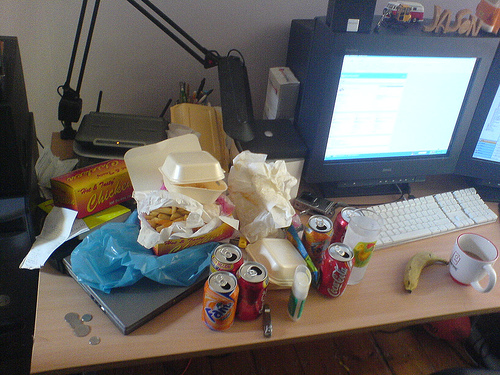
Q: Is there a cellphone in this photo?
A: No, there are no cell phones.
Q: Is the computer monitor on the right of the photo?
A: Yes, the computer monitor is on the right of the image.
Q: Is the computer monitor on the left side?
A: No, the computer monitor is on the right of the image.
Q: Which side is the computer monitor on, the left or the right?
A: The computer monitor is on the right of the image.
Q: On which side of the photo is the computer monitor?
A: The computer monitor is on the right of the image.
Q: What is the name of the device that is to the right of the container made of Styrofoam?
A: The device is a computer monitor.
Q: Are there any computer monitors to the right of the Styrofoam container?
A: Yes, there is a computer monitor to the right of the container.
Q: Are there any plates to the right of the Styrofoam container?
A: No, there is a computer monitor to the right of the container.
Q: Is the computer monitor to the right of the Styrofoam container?
A: Yes, the computer monitor is to the right of the container.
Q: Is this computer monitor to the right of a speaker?
A: No, the computer monitor is to the right of the container.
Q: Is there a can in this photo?
A: Yes, there is a can.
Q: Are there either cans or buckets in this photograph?
A: Yes, there is a can.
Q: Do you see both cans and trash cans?
A: No, there is a can but no trash cans.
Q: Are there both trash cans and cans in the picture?
A: No, there is a can but no trash cans.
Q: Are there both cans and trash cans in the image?
A: No, there is a can but no trash cans.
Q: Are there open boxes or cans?
A: Yes, there is an open can.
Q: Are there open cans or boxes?
A: Yes, there is an open can.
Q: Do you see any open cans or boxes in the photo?
A: Yes, there is an open can.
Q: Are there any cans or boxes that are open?
A: Yes, the can is open.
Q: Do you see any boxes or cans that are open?
A: Yes, the can is open.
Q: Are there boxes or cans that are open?
A: Yes, the can is open.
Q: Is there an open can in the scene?
A: Yes, there is an open can.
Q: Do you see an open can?
A: Yes, there is an open can.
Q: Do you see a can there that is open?
A: Yes, there is a can that is open.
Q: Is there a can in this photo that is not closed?
A: Yes, there is a open can.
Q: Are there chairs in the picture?
A: No, there are no chairs.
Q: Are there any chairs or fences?
A: No, there are no chairs or fences.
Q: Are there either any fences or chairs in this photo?
A: No, there are no chairs or fences.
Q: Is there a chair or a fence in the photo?
A: No, there are no chairs or fences.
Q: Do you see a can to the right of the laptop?
A: Yes, there is a can to the right of the laptop.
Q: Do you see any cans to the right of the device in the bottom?
A: Yes, there is a can to the right of the laptop.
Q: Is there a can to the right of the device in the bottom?
A: Yes, there is a can to the right of the laptop.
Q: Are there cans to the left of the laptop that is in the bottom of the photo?
A: No, the can is to the right of the laptop.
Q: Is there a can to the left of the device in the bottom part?
A: No, the can is to the right of the laptop.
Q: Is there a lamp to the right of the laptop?
A: No, there is a can to the right of the laptop.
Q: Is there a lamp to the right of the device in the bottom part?
A: No, there is a can to the right of the laptop.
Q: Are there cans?
A: Yes, there is a can.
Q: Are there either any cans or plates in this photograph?
A: Yes, there is a can.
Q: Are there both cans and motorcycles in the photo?
A: No, there is a can but no motorcycles.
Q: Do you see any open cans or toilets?
A: Yes, there is an open can.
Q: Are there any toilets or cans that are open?
A: Yes, the can is open.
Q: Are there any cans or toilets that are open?
A: Yes, the can is open.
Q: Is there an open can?
A: Yes, there is an open can.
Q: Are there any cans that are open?
A: Yes, there is a can that is open.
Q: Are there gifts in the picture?
A: No, there are no gifts.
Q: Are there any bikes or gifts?
A: No, there are no gifts or bikes.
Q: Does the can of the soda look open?
A: Yes, the can is open.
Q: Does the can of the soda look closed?
A: No, the can is open.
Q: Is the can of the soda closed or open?
A: The can is open.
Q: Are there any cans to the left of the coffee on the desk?
A: Yes, there is a can to the left of the coffee.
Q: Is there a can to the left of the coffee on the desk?
A: Yes, there is a can to the left of the coffee.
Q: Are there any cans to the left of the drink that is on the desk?
A: Yes, there is a can to the left of the coffee.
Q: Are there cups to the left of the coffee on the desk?
A: No, there is a can to the left of the coffee.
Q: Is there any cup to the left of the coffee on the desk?
A: No, there is a can to the left of the coffee.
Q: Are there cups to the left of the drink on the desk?
A: No, there is a can to the left of the coffee.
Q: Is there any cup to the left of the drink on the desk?
A: No, there is a can to the left of the coffee.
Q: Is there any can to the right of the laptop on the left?
A: Yes, there is a can to the right of the laptop computer.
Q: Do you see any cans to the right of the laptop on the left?
A: Yes, there is a can to the right of the laptop computer.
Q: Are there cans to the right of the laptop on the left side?
A: Yes, there is a can to the right of the laptop computer.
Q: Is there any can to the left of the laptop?
A: No, the can is to the right of the laptop.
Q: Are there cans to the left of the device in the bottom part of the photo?
A: No, the can is to the right of the laptop.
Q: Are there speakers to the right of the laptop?
A: No, there is a can to the right of the laptop.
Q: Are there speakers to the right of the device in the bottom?
A: No, there is a can to the right of the laptop.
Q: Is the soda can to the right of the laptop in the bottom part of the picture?
A: Yes, the can is to the right of the laptop.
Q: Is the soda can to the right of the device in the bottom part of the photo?
A: Yes, the can is to the right of the laptop.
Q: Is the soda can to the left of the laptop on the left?
A: No, the can is to the right of the laptop computer.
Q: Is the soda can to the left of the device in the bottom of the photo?
A: No, the can is to the right of the laptop computer.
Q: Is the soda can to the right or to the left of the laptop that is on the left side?
A: The can is to the right of the laptop.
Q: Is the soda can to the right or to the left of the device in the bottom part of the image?
A: The can is to the right of the laptop.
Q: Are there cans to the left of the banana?
A: Yes, there is a can to the left of the banana.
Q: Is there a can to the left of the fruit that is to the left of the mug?
A: Yes, there is a can to the left of the banana.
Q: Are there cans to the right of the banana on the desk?
A: No, the can is to the left of the banana.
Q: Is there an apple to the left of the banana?
A: No, there is a can to the left of the banana.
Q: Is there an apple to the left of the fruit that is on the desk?
A: No, there is a can to the left of the banana.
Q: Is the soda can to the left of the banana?
A: Yes, the can is to the left of the banana.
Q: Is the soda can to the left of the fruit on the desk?
A: Yes, the can is to the left of the banana.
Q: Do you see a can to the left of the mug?
A: Yes, there is a can to the left of the mug.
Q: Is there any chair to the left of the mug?
A: No, there is a can to the left of the mug.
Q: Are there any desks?
A: Yes, there is a desk.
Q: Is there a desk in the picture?
A: Yes, there is a desk.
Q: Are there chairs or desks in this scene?
A: Yes, there is a desk.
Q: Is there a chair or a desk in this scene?
A: Yes, there is a desk.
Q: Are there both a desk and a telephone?
A: No, there is a desk but no phones.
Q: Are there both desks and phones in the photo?
A: No, there is a desk but no phones.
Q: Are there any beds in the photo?
A: No, there are no beds.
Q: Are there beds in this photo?
A: No, there are no beds.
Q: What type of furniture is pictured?
A: The furniture is a desk.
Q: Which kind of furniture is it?
A: The piece of furniture is a desk.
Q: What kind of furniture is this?
A: This is a desk.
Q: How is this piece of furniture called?
A: This is a desk.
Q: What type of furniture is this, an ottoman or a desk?
A: This is a desk.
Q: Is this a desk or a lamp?
A: This is a desk.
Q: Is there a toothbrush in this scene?
A: No, there are no toothbrushes.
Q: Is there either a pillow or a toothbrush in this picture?
A: No, there are no toothbrushes or pillows.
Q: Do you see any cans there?
A: Yes, there is a can.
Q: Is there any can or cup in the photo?
A: Yes, there is a can.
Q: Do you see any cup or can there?
A: Yes, there is a can.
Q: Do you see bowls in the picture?
A: No, there are no bowls.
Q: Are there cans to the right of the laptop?
A: Yes, there is a can to the right of the laptop.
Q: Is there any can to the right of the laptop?
A: Yes, there is a can to the right of the laptop.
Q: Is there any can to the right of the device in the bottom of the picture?
A: Yes, there is a can to the right of the laptop.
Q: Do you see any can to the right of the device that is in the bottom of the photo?
A: Yes, there is a can to the right of the laptop.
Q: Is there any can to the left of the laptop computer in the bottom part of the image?
A: No, the can is to the right of the laptop.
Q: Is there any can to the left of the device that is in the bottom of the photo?
A: No, the can is to the right of the laptop.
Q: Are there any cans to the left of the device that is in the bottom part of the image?
A: No, the can is to the right of the laptop.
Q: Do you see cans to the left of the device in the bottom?
A: No, the can is to the right of the laptop.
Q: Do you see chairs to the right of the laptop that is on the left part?
A: No, there is a can to the right of the laptop.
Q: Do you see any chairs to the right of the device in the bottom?
A: No, there is a can to the right of the laptop.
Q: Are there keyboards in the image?
A: Yes, there is a keyboard.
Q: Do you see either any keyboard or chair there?
A: Yes, there is a keyboard.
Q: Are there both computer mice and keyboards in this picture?
A: No, there is a keyboard but no computer mice.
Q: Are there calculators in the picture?
A: No, there are no calculators.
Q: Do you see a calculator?
A: No, there are no calculators.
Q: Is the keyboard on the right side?
A: Yes, the keyboard is on the right of the image.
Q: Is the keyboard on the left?
A: No, the keyboard is on the right of the image.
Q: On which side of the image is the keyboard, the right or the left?
A: The keyboard is on the right of the image.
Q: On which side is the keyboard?
A: The keyboard is on the right of the image.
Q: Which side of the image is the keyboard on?
A: The keyboard is on the right of the image.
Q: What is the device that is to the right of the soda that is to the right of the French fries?
A: The device is a keyboard.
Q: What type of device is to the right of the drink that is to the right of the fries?
A: The device is a keyboard.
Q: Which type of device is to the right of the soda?
A: The device is a keyboard.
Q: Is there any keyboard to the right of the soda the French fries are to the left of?
A: Yes, there is a keyboard to the right of the soda.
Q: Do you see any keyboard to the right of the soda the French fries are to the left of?
A: Yes, there is a keyboard to the right of the soda.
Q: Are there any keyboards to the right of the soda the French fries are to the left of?
A: Yes, there is a keyboard to the right of the soda.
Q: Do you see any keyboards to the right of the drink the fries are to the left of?
A: Yes, there is a keyboard to the right of the soda.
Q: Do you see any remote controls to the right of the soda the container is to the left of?
A: No, there is a keyboard to the right of the soda.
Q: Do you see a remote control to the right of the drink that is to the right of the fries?
A: No, there is a keyboard to the right of the soda.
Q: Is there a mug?
A: Yes, there is a mug.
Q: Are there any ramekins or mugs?
A: Yes, there is a mug.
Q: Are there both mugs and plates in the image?
A: No, there is a mug but no plates.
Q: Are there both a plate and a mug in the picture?
A: No, there is a mug but no plates.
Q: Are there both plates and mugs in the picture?
A: No, there is a mug but no plates.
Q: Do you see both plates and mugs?
A: No, there is a mug but no plates.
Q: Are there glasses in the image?
A: No, there are no glasses.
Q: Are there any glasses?
A: No, there are no glasses.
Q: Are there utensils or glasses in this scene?
A: No, there are no glasses or utensils.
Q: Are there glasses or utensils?
A: No, there are no glasses or utensils.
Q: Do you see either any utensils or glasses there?
A: No, there are no glasses or utensils.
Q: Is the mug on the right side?
A: Yes, the mug is on the right of the image.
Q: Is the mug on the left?
A: No, the mug is on the right of the image.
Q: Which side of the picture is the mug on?
A: The mug is on the right of the image.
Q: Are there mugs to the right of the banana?
A: Yes, there is a mug to the right of the banana.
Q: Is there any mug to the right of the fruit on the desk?
A: Yes, there is a mug to the right of the banana.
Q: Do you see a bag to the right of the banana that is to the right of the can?
A: No, there is a mug to the right of the banana.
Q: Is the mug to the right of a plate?
A: No, the mug is to the right of the banana.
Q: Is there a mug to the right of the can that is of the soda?
A: Yes, there is a mug to the right of the can.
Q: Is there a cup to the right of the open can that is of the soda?
A: No, there is a mug to the right of the can.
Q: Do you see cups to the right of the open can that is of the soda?
A: No, there is a mug to the right of the can.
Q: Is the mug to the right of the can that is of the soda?
A: Yes, the mug is to the right of the can.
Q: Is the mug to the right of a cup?
A: No, the mug is to the right of the can.